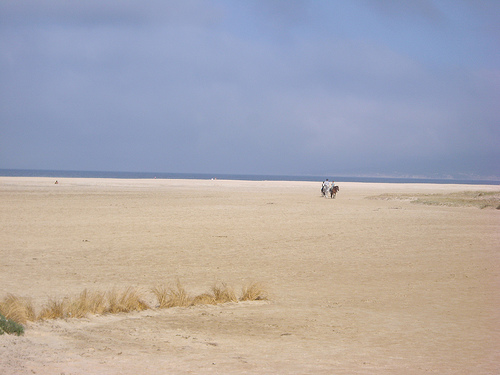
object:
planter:
[313, 175, 498, 183]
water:
[2, 167, 498, 186]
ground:
[1, 178, 495, 374]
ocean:
[0, 172, 498, 181]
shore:
[1, 175, 496, 186]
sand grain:
[260, 228, 265, 230]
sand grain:
[222, 222, 228, 224]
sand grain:
[217, 230, 223, 233]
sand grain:
[172, 217, 176, 219]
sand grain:
[172, 227, 175, 229]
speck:
[52, 178, 59, 185]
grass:
[36, 282, 231, 342]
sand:
[2, 184, 499, 373]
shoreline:
[1, 176, 498, 191]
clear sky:
[55, 19, 486, 139]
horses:
[319, 185, 340, 199]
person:
[320, 178, 339, 199]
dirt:
[358, 224, 460, 286]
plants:
[23, 275, 268, 317]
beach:
[88, 177, 255, 273]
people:
[321, 177, 340, 198]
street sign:
[211, 176, 219, 182]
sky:
[0, 0, 499, 180]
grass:
[45, 281, 99, 327]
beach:
[5, 188, 475, 285]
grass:
[0, 274, 271, 334]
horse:
[329, 185, 340, 198]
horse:
[320, 184, 329, 198]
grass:
[2, 279, 48, 336]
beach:
[2, 176, 499, 374]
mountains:
[298, 170, 498, 180]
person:
[329, 177, 334, 190]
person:
[318, 179, 327, 189]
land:
[304, 170, 499, 182]